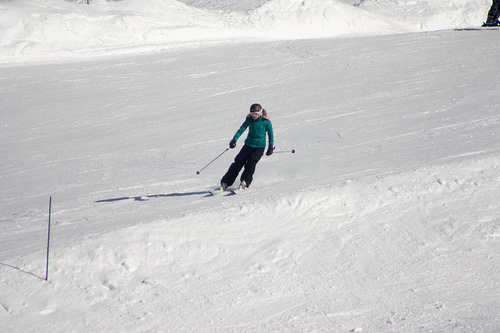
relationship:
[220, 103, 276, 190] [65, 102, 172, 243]
lady on hill